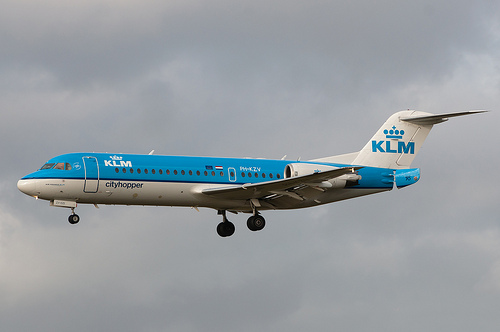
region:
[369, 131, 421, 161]
'klm' in sky blue, all caps, on tail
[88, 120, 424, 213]
klm royal dutch airlines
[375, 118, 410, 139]
logo is sky blue crown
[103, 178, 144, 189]
klm 'cityhopper'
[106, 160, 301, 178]
round passenger windows, black in flight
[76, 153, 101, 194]
tall door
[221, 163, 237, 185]
emergency exit, white & round around window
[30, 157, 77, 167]
pilots'/cockpit's long wide windscreen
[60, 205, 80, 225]
landing gear is up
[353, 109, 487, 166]
elevators on rudder [?]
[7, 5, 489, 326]
The sky is cloudy.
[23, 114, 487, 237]
The airplane is flying.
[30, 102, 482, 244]
The airplane is in the sky.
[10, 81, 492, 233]
The airplane is blue.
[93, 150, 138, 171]
The lettering is white.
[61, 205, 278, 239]
The wheels are black.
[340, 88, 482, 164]
The tail is white.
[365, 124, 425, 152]
The lettering is blue.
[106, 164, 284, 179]
The windows are small.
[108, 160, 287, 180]
The windows are on the side of the plane.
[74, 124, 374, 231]
blue and white plane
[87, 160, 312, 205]
long row of windows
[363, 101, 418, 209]
white tail with logo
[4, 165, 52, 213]
white nose on plane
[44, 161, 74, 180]
small windows in cockpit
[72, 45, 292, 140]
sky is grey and cloudy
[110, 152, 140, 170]
white logo on front of plane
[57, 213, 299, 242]
plane has lowered wheels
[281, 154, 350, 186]
white engine on plane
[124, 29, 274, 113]
thick and rainy clouds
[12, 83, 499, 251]
plane in the sky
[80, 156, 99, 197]
door on the plane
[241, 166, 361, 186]
wing of the plane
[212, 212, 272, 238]
wheels on the plane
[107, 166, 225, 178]
windows on the plane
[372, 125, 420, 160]
klm logo on the plane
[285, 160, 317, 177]
engine of the plane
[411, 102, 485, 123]
back wing on the plane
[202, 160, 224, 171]
flags on the plane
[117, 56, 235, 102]
gray black cloudy sky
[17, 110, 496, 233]
a KLM airplane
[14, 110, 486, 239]
a white and aqua plane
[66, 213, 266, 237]
the landing gear of the plane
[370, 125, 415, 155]
the KLM logo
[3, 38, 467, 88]
a cloudy sky in the background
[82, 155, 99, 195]
the exit door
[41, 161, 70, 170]
the pilot cabin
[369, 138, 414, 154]
the word KLM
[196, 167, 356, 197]
a wing of the plane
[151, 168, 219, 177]
the passengers window